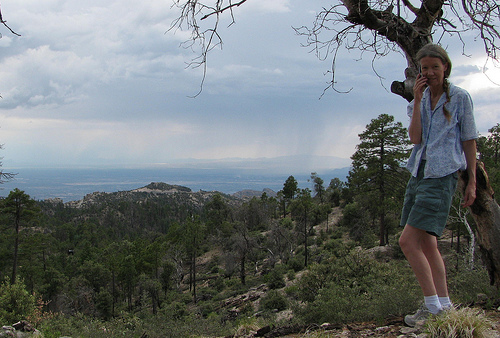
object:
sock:
[422, 294, 444, 314]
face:
[417, 55, 444, 84]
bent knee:
[397, 236, 416, 248]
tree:
[165, 0, 500, 293]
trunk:
[396, 27, 499, 301]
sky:
[0, 0, 500, 163]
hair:
[416, 43, 451, 126]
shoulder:
[449, 87, 467, 95]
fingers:
[413, 82, 428, 93]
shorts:
[399, 157, 456, 237]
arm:
[458, 87, 477, 189]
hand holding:
[414, 73, 430, 97]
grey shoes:
[401, 307, 448, 326]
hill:
[70, 181, 242, 224]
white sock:
[438, 294, 452, 308]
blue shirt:
[403, 82, 475, 178]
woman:
[397, 42, 476, 326]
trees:
[341, 112, 416, 248]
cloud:
[0, 0, 500, 129]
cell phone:
[416, 61, 425, 81]